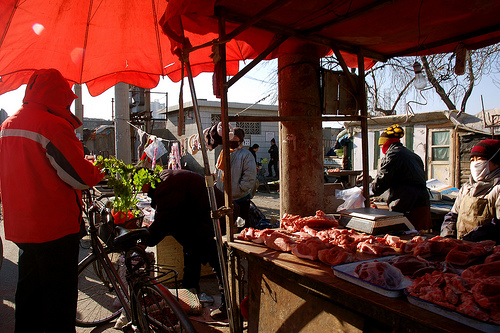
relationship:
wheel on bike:
[133, 282, 209, 330] [67, 172, 239, 331]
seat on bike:
[104, 217, 155, 249] [68, 181, 200, 331]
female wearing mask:
[445, 132, 499, 251] [466, 157, 493, 179]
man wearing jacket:
[0, 67, 106, 331] [0, 55, 103, 247]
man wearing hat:
[366, 122, 434, 233] [373, 121, 412, 153]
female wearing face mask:
[442, 137, 500, 243] [470, 159, 489, 184]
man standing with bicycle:
[0, 67, 106, 331] [78, 185, 179, 329]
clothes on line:
[135, 134, 208, 177] [127, 122, 267, 154]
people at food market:
[215, 127, 498, 232] [50, 86, 385, 283]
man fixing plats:
[125, 157, 235, 292] [90, 212, 323, 328]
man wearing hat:
[140, 168, 234, 321] [380, 123, 398, 146]